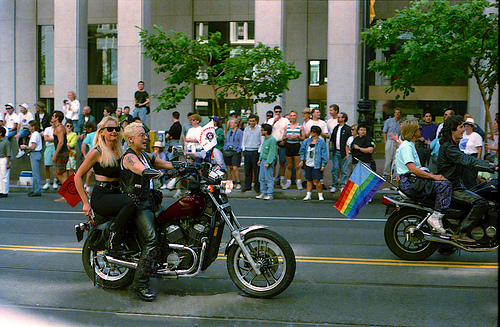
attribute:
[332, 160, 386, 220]
flag — rainbow, pride, blowing, colorful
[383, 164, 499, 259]
motorcycle — black, chrome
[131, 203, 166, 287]
chaps — black, leather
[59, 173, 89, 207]
flag — red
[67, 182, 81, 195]
circle — black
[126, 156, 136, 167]
tattoo — dark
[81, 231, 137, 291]
tire — black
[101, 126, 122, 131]
sunglasses — dark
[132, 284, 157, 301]
boot — black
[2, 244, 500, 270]
line — yellow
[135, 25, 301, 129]
tree — green, small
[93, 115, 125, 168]
hair — blond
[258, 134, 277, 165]
shirt — green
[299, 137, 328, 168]
jacket — blue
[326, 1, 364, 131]
pillar — light colored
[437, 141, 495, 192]
jacket — black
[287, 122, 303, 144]
shirt — blue, striped, white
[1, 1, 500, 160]
building — large